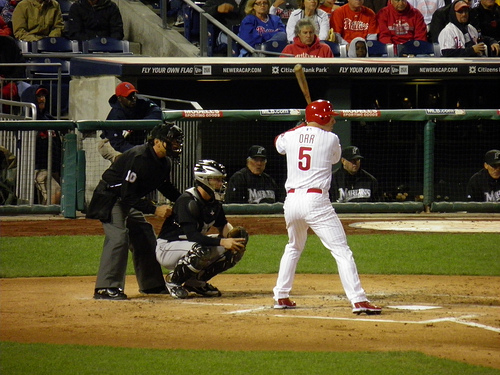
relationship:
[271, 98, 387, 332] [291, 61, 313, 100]
baseball player holding bat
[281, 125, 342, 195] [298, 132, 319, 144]
jersey has name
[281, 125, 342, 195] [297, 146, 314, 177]
jersey has a number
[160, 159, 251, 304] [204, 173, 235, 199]
catcher has a mask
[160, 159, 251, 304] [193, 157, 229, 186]
catcher wearing a helmet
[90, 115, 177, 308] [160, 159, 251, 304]
umpire behind catcher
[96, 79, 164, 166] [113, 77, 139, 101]
man wearing hat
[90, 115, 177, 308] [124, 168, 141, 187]
umpire has number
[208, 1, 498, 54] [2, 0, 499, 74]
fans are sitting in bleachers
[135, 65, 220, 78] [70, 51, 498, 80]
words on dugout roof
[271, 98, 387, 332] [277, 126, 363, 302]
baseball player has uniform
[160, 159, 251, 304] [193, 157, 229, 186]
catcher wearing helmet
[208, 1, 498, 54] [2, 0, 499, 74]
fans sitting in bleachers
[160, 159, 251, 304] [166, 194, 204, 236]
catcher wearing black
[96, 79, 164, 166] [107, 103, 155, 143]
man wearing sweatshirt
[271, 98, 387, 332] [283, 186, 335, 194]
baseball player wearing a belt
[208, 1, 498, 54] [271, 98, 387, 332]
fans are watching baseball player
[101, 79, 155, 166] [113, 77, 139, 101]
man wearing hat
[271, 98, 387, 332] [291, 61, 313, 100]
baseball player about to swing a bat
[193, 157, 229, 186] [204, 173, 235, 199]
helmet has a mask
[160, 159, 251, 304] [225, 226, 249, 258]
catcher holding glove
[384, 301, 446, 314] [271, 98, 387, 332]
home plate near baseball player